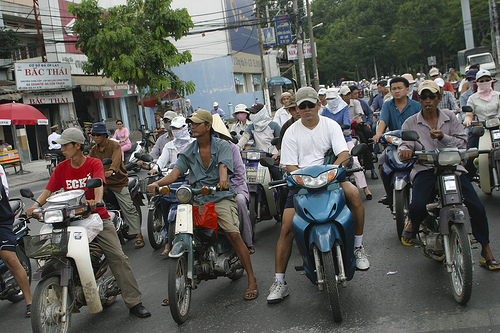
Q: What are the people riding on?
A: Scooters and mopeds.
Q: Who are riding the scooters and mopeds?
A: The people.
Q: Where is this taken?
A: A city street.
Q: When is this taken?
A: Daytime.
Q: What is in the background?
A: Trees and buildings.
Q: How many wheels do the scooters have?
A: Two.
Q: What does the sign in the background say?
A: Bac Thai.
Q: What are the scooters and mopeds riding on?
A: The pavement.